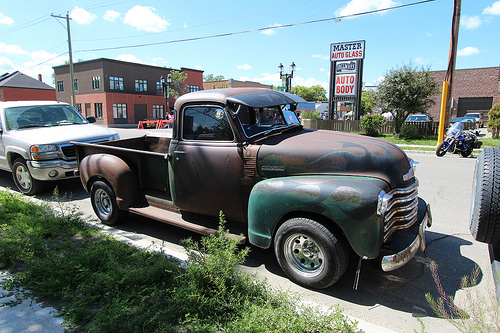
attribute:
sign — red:
[132, 112, 173, 128]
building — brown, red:
[388, 66, 498, 137]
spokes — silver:
[283, 230, 327, 277]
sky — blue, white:
[98, 0, 193, 48]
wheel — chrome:
[270, 215, 353, 290]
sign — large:
[331, 41, 361, 101]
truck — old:
[78, 54, 447, 301]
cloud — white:
[331, 2, 394, 13]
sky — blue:
[0, 1, 498, 86]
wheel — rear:
[90, 179, 119, 224]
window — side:
[179, 105, 234, 143]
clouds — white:
[96, 4, 168, 38]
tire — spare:
[467, 146, 499, 244]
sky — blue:
[16, 10, 485, 79]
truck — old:
[71, 77, 430, 292]